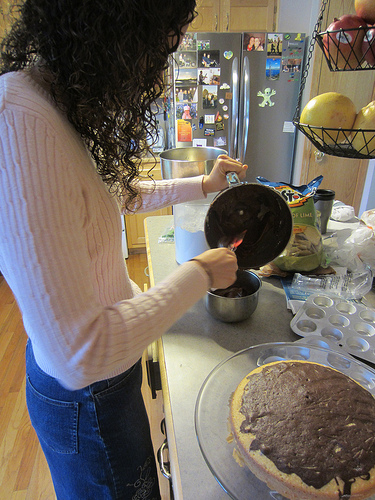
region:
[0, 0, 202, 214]
a woman's dark curly hair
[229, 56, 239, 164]
a refrigerator door handle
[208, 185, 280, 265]
chocolate cake icing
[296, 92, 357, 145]
a large grapefruit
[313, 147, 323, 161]
a gold doorknob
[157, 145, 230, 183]
a large silver bowl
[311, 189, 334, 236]
a black and gray coffee mug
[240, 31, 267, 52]
a picture of two women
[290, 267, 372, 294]
a clear plastic bag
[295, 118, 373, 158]
a black basket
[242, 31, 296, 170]
stainless steel refrigerator door with magnets and photos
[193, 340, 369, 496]
cake placed on clear glass plate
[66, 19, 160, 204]
long curly dark hair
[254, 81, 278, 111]
neon yellow alien decoration of refrigerator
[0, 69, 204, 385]
baby pink cable knit sweater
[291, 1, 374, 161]
apples and grapefruit in hanging basket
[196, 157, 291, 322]
woman is making frosting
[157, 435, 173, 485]
chrome drawer pulls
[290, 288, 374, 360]
clean, steel muffin pan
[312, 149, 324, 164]
crystal knob on pantry door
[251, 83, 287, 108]
green ghost on door of fridge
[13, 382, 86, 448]
back pocket on blue jeans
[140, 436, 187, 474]
silver handle of drawer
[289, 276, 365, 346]
silver cup cake tin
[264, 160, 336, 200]
top of chip bag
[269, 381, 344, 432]
chocolate frosting on top of cake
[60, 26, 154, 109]
woman's curly black hair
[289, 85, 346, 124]
yellow grapefruit in basket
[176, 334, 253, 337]
shiny silver counter top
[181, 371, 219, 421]
edge of clear cake holder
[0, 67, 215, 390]
a woman's long sleeve sweater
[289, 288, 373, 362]
a cupcake pan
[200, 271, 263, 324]
a small silver bowl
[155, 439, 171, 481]
a silver drawer handle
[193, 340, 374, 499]
a glass plate dish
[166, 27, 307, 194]
a large stainless steel refrigerator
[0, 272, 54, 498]
light brown hardwood floor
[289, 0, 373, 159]
a black hanging basket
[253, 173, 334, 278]
a bag of chips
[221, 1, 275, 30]
a brown cabinet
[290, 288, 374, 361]
silver muffin pan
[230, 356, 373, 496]
yellow cake with chocolate frosting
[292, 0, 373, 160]
black metal hanging basket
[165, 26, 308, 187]
stainless steel fridge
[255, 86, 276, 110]
green man magnet on fridge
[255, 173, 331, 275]
bag of Tostitos chips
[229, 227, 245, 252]
orange spatula inside bowl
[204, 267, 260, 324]
silver bowl on counter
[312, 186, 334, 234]
silver coffee cup with black lid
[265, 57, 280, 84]
blue picture on the fridge